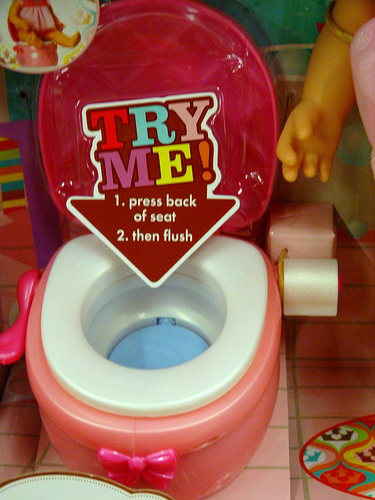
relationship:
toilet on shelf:
[22, 233, 283, 499] [11, 336, 314, 495]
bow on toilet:
[93, 434, 180, 496] [5, 14, 297, 489]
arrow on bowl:
[66, 88, 238, 288] [40, 233, 267, 419]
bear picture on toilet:
[7, 0, 80, 49] [22, 233, 283, 499]